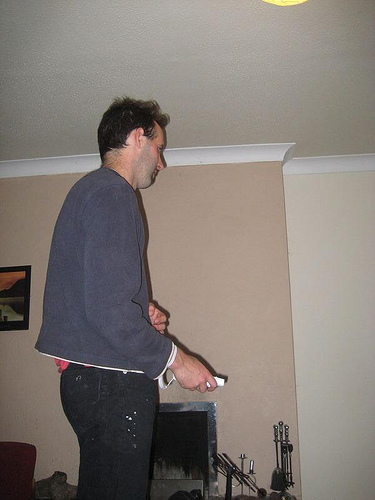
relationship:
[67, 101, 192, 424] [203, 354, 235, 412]
man holding controller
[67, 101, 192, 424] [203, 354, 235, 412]
man with controller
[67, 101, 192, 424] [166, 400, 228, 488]
man near fireplace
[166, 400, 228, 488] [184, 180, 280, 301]
fireplace on wall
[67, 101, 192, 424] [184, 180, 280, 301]
man near wall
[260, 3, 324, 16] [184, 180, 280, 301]
light above wall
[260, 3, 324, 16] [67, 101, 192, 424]
light above man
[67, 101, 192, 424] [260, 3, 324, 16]
man near light